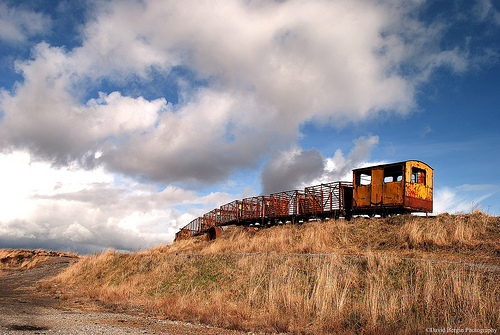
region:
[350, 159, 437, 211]
a yellow train car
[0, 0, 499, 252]
a cloudy blue sky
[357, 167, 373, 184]
the window of a train car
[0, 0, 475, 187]
a large gray and white cloud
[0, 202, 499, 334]
a yellow grassy field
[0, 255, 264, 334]
a gray gravel road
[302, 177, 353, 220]
a red mesh train car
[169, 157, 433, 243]
a train on the tracks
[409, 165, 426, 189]
a rear train window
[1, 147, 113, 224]
a bright cloudy patch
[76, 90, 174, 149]
this is a cloud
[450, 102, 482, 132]
this is the sky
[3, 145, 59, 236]
this is the sun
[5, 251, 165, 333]
this is a road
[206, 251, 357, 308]
this is dead grass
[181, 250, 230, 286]
green and brown grass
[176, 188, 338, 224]
large empty train cars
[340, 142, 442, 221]
abandoned yellow train engine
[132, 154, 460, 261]
a very long train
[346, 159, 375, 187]
a medium sized window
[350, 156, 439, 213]
a train car of plywood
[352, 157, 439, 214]
a train car of wood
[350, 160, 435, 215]
a train car made of plywood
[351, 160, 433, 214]
a train car made of wood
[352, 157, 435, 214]
a train car with a curved roof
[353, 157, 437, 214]
a train car with open windows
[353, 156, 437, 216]
a train car with no glass in the windows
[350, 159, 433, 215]
a train car with brown paint on the lower back end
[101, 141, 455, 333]
train on a small hill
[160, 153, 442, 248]
train taking a curve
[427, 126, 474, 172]
this is the sky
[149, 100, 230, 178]
this is a gray cloud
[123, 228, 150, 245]
this is a white cloud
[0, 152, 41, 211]
this is the sun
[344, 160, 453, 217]
this is a yellow cart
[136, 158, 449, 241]
this is an abandoned train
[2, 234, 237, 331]
this is the road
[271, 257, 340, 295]
this is dead grass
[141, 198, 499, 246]
these are train tracks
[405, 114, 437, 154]
this is the color blue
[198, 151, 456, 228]
yellow train with empth cage cars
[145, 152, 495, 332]
train track is on a small hill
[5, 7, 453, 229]
clouds in the sky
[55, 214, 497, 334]
grass on the hill is dry and brown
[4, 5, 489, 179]
sky is blue with shite clouds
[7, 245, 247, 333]
rock path to the side of the track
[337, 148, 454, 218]
last car on the train is rusting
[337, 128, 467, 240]
last train car is painted yellow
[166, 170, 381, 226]
the cars on this train look like cages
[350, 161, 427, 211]
there are several windows on the yellow train car